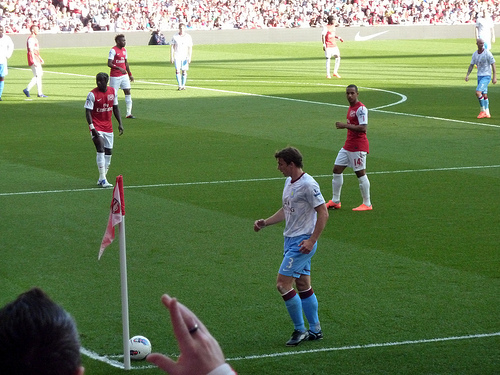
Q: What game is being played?
A: Soccer.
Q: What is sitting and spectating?
A: The crowd.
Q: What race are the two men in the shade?
A: African American.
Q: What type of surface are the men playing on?
A: Soccer field.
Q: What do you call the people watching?
A: Spectators.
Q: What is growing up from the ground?
A: Grass.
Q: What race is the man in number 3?
A: Caucasian.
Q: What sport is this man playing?
A: Soccer.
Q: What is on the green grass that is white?
A: Lines.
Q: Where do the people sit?
A: In the stands.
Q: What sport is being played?
A: Soccer.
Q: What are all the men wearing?
A: Uniforms.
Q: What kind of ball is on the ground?
A: Soccer ball.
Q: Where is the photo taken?
A: In the field.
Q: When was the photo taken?
A: Daytime.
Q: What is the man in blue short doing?
A: Going to kick the ball.